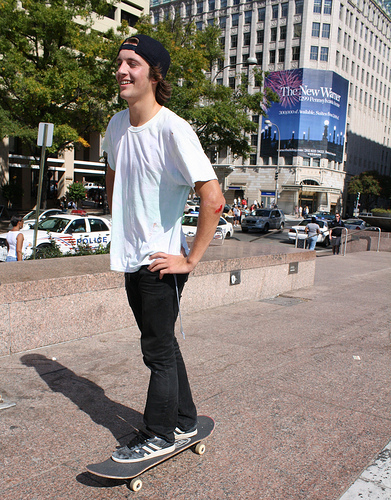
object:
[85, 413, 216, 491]
skateboard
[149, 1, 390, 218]
building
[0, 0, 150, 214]
building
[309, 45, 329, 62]
window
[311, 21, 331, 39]
window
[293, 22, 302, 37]
window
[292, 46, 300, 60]
window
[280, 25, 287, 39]
window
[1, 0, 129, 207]
tree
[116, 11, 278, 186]
tree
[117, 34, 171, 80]
cap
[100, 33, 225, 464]
man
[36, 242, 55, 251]
wheel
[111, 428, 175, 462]
shoe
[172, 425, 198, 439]
shoe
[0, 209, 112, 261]
police car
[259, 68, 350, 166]
banner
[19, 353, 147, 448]
shadow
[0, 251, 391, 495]
ground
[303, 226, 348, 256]
handrail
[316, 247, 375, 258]
stairs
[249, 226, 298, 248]
handrail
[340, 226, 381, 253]
handrail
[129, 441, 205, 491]
wheels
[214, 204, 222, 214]
cut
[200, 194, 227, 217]
elbow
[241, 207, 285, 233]
suv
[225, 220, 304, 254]
road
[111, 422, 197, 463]
shoes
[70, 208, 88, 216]
light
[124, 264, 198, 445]
jeans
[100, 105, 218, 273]
shirt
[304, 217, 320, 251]
woma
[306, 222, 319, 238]
shirt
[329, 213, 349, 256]
man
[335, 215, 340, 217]
glasses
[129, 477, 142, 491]
wheel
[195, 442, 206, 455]
wheel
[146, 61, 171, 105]
hair